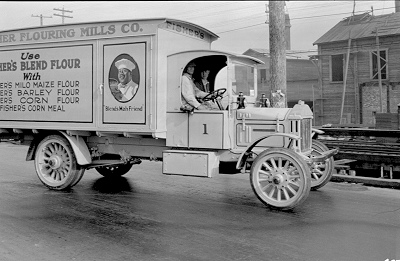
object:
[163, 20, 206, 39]
name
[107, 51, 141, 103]
picture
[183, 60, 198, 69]
hat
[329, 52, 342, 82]
window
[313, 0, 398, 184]
building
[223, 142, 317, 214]
wheel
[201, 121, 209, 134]
1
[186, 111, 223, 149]
door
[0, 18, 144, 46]
company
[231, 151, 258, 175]
guard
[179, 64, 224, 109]
driver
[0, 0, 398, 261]
picture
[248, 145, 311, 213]
trie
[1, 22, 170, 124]
cargo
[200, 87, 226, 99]
steering wheel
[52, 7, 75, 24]
telephone poles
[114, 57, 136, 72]
baker's hat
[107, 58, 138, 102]
baker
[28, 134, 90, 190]
tires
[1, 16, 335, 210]
truck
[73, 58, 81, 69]
writing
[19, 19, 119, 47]
flowering mills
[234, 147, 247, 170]
edge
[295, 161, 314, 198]
edge